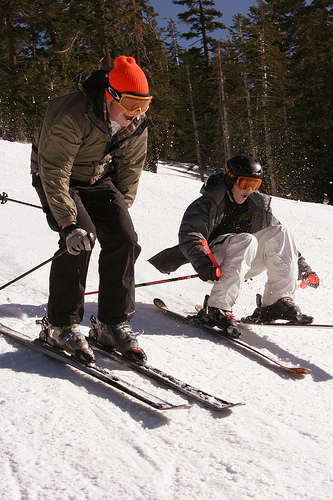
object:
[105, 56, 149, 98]
beanie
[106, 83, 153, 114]
goggle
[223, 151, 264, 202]
helmet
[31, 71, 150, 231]
jacket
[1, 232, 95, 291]
pole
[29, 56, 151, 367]
man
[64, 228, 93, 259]
hand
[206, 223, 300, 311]
pants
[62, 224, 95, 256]
glove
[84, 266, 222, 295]
pole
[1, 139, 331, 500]
trail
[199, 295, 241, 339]
boot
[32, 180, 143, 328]
pants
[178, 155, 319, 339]
man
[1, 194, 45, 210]
pole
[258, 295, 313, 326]
boot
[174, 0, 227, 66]
trees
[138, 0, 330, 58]
sky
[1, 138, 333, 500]
snow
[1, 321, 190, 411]
ski